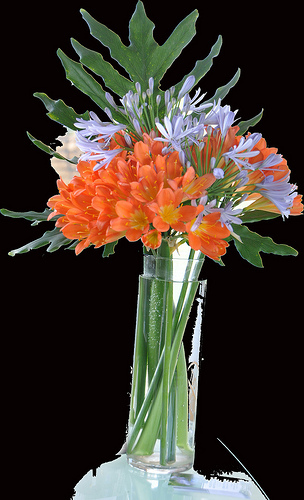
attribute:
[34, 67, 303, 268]
flowers — cluster, orange, white, arrangement, purple, colorful, vivid, spiky, tubular, yellow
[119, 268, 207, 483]
vase — clear, cylindrical, a part, an edge, narrow, glass, reflection, circular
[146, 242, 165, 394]
stems — thick, green, a part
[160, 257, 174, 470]
stems — thick, green, a part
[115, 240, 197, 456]
stems — thick, green, a part, side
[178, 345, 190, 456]
stems — thick, green, a part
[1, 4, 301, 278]
leaves — broad, green, part, a part, long, thin, spotty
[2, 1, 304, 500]
background — black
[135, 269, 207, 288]
line — a part